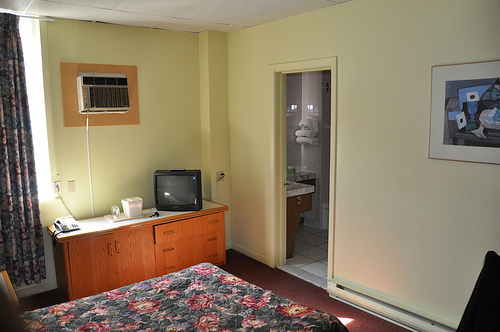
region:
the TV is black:
[152, 165, 222, 226]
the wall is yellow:
[341, 66, 406, 253]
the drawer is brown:
[62, 243, 244, 277]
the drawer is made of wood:
[83, 238, 239, 290]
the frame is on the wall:
[418, 53, 494, 164]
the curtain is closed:
[3, 15, 63, 290]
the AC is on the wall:
[56, 46, 169, 142]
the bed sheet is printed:
[59, 295, 292, 326]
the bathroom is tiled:
[301, 224, 324, 275]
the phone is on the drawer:
[52, 210, 93, 243]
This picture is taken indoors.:
[23, 19, 494, 315]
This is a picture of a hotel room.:
[14, 13, 443, 330]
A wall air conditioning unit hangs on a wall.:
[59, 41, 204, 153]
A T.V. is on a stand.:
[146, 144, 251, 262]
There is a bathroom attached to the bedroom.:
[280, 87, 342, 283]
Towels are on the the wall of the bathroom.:
[286, 98, 335, 165]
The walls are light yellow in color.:
[341, 7, 419, 328]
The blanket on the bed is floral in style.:
[142, 278, 281, 330]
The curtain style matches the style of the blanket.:
[0, 31, 57, 290]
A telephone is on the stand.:
[49, 210, 111, 265]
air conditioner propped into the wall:
[72, 63, 140, 120]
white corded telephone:
[50, 205, 85, 250]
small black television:
[145, 160, 210, 222]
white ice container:
[118, 192, 147, 222]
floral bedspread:
[12, 250, 348, 328]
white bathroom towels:
[290, 115, 320, 150]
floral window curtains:
[0, 21, 61, 281]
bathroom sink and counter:
[277, 164, 320, 257]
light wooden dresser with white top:
[61, 190, 231, 302]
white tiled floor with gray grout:
[288, 219, 337, 283]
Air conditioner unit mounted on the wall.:
[73, 69, 135, 116]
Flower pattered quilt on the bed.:
[16, 257, 346, 329]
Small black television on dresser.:
[153, 166, 204, 213]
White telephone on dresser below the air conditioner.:
[52, 216, 80, 231]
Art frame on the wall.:
[431, 62, 498, 161]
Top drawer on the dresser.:
[155, 215, 224, 234]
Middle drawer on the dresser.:
[154, 231, 234, 252]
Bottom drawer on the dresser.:
[161, 262, 226, 269]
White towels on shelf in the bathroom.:
[295, 112, 321, 145]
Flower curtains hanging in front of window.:
[1, 14, 46, 283]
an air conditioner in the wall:
[74, 70, 136, 115]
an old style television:
[150, 165, 207, 216]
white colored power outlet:
[211, 168, 227, 185]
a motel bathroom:
[274, 71, 335, 277]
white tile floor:
[301, 238, 324, 264]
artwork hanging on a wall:
[426, 62, 498, 164]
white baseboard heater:
[328, 272, 430, 327]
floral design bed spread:
[158, 285, 238, 325]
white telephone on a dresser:
[53, 212, 85, 237]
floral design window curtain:
[1, 23, 36, 258]